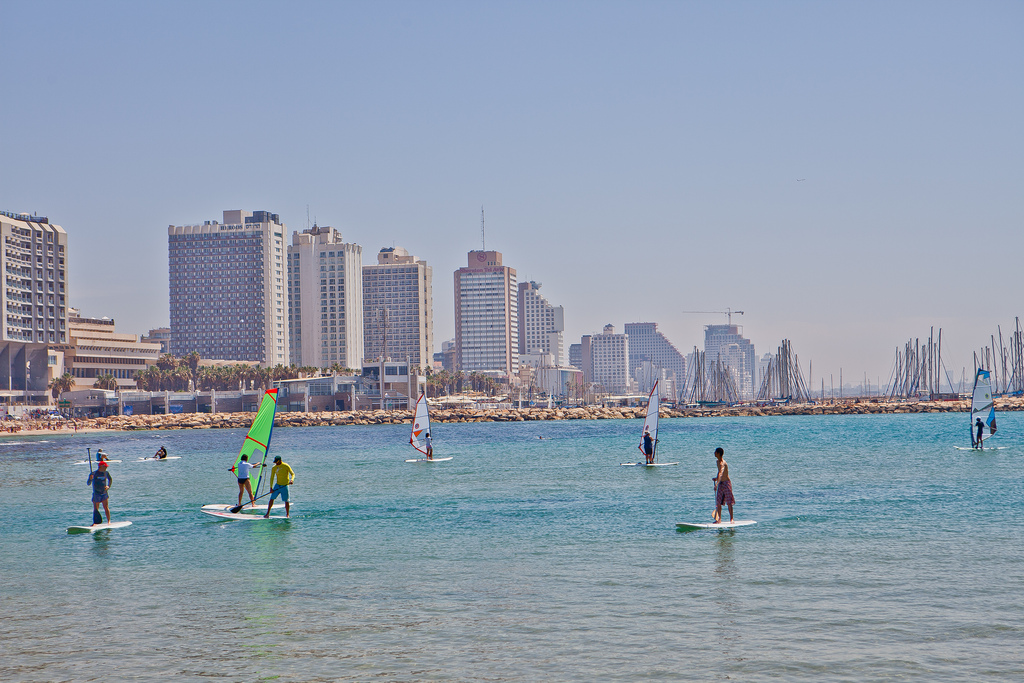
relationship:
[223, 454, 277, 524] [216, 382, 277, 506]
person on sailboard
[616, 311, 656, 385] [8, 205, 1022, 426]
building in city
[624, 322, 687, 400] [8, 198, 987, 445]
building in city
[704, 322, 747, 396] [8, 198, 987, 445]
building in city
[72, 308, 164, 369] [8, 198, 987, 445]
building in city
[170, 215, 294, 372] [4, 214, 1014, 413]
building in city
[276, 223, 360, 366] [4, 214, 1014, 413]
building in city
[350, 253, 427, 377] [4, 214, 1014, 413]
building in city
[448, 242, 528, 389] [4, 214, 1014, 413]
building in city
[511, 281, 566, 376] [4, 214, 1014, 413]
building in city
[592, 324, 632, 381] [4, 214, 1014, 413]
building in city